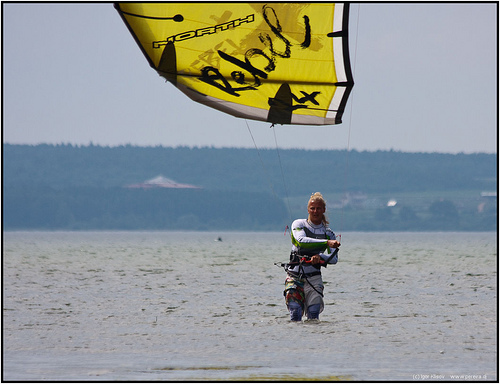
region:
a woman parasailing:
[104, 6, 360, 319]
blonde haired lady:
[302, 188, 332, 222]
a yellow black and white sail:
[107, 2, 357, 127]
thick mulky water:
[6, 232, 496, 381]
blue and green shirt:
[287, 219, 344, 264]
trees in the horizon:
[5, 139, 499, 184]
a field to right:
[380, 190, 483, 202]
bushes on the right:
[374, 193, 477, 223]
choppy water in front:
[6, 260, 491, 331]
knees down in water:
[289, 316, 335, 337]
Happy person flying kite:
[281, 192, 343, 320]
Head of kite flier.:
[305, 193, 327, 221]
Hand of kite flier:
[326, 236, 341, 247]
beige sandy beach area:
[85, 262, 152, 292]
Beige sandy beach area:
[377, 254, 440, 286]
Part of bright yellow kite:
[113, 9, 368, 130]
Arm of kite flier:
[293, 227, 323, 248]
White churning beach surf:
[146, 172, 198, 193]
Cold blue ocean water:
[28, 172, 85, 199]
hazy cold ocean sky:
[23, 82, 110, 113]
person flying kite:
[283, 182, 338, 331]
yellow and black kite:
[138, 6, 368, 134]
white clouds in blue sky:
[9, 13, 69, 60]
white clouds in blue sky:
[58, 17, 120, 68]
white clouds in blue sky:
[13, 50, 63, 90]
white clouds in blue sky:
[61, 48, 138, 146]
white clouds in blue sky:
[354, 23, 411, 72]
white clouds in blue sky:
[412, 10, 464, 59]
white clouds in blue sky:
[354, 60, 398, 114]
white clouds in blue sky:
[386, 75, 456, 145]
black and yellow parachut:
[114, 3, 352, 123]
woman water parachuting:
[285, 191, 342, 318]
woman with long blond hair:
[305, 192, 327, 229]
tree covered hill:
[11, 140, 493, 227]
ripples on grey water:
[31, 254, 121, 300]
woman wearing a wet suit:
[283, 190, 339, 319]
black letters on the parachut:
[199, 3, 319, 94]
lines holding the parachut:
[250, 114, 367, 269]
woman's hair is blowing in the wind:
[304, 189, 330, 230]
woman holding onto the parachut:
[280, 235, 345, 274]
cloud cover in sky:
[6, 4, 496, 137]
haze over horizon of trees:
[3, 141, 498, 188]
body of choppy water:
[8, 229, 492, 381]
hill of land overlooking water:
[4, 157, 494, 382]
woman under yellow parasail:
[117, 2, 353, 324]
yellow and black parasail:
[118, 2, 354, 126]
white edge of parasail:
[148, 43, 356, 128]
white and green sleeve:
[287, 193, 339, 262]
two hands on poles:
[281, 237, 341, 291]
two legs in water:
[284, 273, 327, 332]